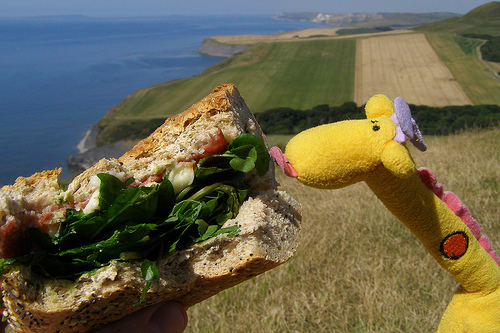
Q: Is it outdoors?
A: Yes, it is outdoors.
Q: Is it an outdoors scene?
A: Yes, it is outdoors.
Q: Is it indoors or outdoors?
A: It is outdoors.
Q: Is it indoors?
A: No, it is outdoors.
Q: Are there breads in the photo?
A: Yes, there is a bread.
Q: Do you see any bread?
A: Yes, there is a bread.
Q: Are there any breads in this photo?
A: Yes, there is a bread.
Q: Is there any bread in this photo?
A: Yes, there is a bread.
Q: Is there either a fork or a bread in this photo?
A: Yes, there is a bread.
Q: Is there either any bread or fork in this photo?
A: Yes, there is a bread.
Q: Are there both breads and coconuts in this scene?
A: No, there is a bread but no coconuts.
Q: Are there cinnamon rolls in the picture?
A: No, there are no cinnamon rolls.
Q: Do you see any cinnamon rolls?
A: No, there are no cinnamon rolls.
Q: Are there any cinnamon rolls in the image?
A: No, there are no cinnamon rolls.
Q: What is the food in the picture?
A: The food is a bread.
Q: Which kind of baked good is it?
A: The food is a bread.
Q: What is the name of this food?
A: This is a bread.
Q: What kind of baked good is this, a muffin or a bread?
A: This is a bread.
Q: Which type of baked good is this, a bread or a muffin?
A: This is a bread.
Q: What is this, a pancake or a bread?
A: This is a bread.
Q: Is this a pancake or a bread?
A: This is a bread.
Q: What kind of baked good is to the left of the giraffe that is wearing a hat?
A: The food is a bread.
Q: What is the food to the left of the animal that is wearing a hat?
A: The food is a bread.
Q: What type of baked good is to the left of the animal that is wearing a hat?
A: The food is a bread.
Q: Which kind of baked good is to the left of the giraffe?
A: The food is a bread.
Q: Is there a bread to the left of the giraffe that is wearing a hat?
A: Yes, there is a bread to the left of the giraffe.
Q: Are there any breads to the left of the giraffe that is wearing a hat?
A: Yes, there is a bread to the left of the giraffe.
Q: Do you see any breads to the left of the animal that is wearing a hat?
A: Yes, there is a bread to the left of the giraffe.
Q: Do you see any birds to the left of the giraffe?
A: No, there is a bread to the left of the giraffe.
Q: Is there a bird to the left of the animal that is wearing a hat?
A: No, there is a bread to the left of the giraffe.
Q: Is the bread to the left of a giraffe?
A: Yes, the bread is to the left of a giraffe.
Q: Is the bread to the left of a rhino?
A: No, the bread is to the left of a giraffe.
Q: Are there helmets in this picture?
A: No, there are no helmets.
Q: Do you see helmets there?
A: No, there are no helmets.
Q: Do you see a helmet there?
A: No, there are no helmets.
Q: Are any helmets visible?
A: No, there are no helmets.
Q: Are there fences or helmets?
A: No, there are no helmets or fences.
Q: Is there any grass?
A: Yes, there is grass.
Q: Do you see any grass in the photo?
A: Yes, there is grass.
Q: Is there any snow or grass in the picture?
A: Yes, there is grass.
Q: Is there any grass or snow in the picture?
A: Yes, there is grass.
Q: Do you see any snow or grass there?
A: Yes, there is grass.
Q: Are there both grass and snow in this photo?
A: No, there is grass but no snow.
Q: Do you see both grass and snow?
A: No, there is grass but no snow.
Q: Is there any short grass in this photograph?
A: Yes, there is short grass.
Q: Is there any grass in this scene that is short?
A: Yes, there is grass that is short.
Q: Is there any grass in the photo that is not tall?
A: Yes, there is short grass.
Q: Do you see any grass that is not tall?
A: Yes, there is short grass.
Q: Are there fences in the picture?
A: No, there are no fences.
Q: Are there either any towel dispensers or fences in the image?
A: No, there are no fences or towel dispensers.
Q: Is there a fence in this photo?
A: No, there are no fences.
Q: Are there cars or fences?
A: No, there are no fences or cars.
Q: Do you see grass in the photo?
A: Yes, there is grass.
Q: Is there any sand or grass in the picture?
A: Yes, there is grass.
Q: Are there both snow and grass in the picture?
A: No, there is grass but no snow.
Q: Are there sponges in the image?
A: No, there are no sponges.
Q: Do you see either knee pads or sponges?
A: No, there are no sponges or knee pads.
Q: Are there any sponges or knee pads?
A: No, there are no sponges or knee pads.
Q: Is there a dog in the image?
A: No, there are no dogs.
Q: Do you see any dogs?
A: No, there are no dogs.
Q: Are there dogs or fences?
A: No, there are no dogs or fences.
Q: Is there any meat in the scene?
A: Yes, there is meat.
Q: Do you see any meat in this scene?
A: Yes, there is meat.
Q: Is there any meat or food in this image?
A: Yes, there is meat.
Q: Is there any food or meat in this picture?
A: Yes, there is meat.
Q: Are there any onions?
A: No, there are no onions.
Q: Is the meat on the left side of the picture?
A: Yes, the meat is on the left of the image.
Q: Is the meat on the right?
A: No, the meat is on the left of the image.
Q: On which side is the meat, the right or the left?
A: The meat is on the left of the image.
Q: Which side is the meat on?
A: The meat is on the left of the image.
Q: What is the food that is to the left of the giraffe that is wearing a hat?
A: The food is meat.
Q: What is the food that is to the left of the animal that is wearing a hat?
A: The food is meat.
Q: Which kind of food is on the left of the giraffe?
A: The food is meat.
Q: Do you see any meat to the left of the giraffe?
A: Yes, there is meat to the left of the giraffe.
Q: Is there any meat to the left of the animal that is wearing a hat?
A: Yes, there is meat to the left of the giraffe.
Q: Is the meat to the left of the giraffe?
A: Yes, the meat is to the left of the giraffe.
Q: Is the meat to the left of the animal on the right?
A: Yes, the meat is to the left of the giraffe.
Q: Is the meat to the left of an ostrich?
A: No, the meat is to the left of the giraffe.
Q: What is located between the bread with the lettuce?
A: The meat is between the bread.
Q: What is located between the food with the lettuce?
A: The meat is between the bread.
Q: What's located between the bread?
A: The meat is between the bread.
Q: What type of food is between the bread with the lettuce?
A: The food is meat.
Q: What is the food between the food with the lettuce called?
A: The food is meat.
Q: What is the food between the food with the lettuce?
A: The food is meat.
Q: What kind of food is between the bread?
A: The food is meat.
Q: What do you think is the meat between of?
A: The meat is between the bread.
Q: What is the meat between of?
A: The meat is between the bread.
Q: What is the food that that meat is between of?
A: The food is a bread.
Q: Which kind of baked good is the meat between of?
A: The meat is between the bread.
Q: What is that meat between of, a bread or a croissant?
A: The meat is between a bread.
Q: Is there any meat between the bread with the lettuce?
A: Yes, there is meat between the bread.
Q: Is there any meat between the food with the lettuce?
A: Yes, there is meat between the bread.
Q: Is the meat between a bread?
A: Yes, the meat is between a bread.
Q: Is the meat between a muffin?
A: No, the meat is between a bread.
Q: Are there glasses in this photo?
A: No, there are no glasses.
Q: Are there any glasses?
A: No, there are no glasses.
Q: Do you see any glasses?
A: No, there are no glasses.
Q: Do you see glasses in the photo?
A: No, there are no glasses.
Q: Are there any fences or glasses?
A: No, there are no glasses or fences.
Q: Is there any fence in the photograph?
A: No, there are no fences.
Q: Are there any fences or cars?
A: No, there are no fences or cars.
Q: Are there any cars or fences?
A: No, there are no fences or cars.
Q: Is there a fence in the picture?
A: No, there are no fences.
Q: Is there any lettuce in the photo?
A: Yes, there is lettuce.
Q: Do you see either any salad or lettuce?
A: Yes, there is lettuce.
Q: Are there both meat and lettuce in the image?
A: Yes, there are both lettuce and meat.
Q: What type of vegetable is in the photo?
A: The vegetable is lettuce.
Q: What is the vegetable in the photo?
A: The vegetable is lettuce.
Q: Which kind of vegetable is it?
A: The vegetable is lettuce.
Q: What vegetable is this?
A: This is lettuce.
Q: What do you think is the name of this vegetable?
A: This is lettuce.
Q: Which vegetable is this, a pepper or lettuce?
A: This is lettuce.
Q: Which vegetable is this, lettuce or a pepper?
A: This is lettuce.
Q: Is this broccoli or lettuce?
A: This is lettuce.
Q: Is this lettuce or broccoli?
A: This is lettuce.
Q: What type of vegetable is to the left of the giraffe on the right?
A: The vegetable is lettuce.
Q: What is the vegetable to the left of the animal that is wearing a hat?
A: The vegetable is lettuce.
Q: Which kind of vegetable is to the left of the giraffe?
A: The vegetable is lettuce.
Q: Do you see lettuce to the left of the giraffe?
A: Yes, there is lettuce to the left of the giraffe.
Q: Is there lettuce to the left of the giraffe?
A: Yes, there is lettuce to the left of the giraffe.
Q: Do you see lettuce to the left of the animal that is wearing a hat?
A: Yes, there is lettuce to the left of the giraffe.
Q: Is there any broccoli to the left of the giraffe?
A: No, there is lettuce to the left of the giraffe.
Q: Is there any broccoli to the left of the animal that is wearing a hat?
A: No, there is lettuce to the left of the giraffe.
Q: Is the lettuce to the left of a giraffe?
A: Yes, the lettuce is to the left of a giraffe.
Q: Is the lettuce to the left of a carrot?
A: No, the lettuce is to the left of a giraffe.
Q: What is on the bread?
A: The lettuce is on the bread.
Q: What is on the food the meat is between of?
A: The lettuce is on the bread.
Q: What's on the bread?
A: The lettuce is on the bread.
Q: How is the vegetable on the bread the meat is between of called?
A: The vegetable is lettuce.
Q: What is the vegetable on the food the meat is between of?
A: The vegetable is lettuce.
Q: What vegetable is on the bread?
A: The vegetable is lettuce.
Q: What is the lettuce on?
A: The lettuce is on the bread.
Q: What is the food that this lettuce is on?
A: The food is a bread.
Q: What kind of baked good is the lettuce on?
A: The lettuce is on the bread.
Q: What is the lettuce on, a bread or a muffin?
A: The lettuce is on a bread.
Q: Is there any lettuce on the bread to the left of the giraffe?
A: Yes, there is lettuce on the bread.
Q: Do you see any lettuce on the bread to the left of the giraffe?
A: Yes, there is lettuce on the bread.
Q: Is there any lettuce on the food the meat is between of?
A: Yes, there is lettuce on the bread.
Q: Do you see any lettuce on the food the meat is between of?
A: Yes, there is lettuce on the bread.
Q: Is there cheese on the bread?
A: No, there is lettuce on the bread.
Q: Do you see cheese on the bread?
A: No, there is lettuce on the bread.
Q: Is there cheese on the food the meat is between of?
A: No, there is lettuce on the bread.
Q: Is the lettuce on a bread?
A: Yes, the lettuce is on a bread.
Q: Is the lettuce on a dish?
A: No, the lettuce is on a bread.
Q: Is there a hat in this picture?
A: Yes, there is a hat.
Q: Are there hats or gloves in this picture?
A: Yes, there is a hat.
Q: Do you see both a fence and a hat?
A: No, there is a hat but no fences.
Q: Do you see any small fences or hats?
A: Yes, there is a small hat.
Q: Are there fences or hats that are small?
A: Yes, the hat is small.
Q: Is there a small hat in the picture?
A: Yes, there is a small hat.